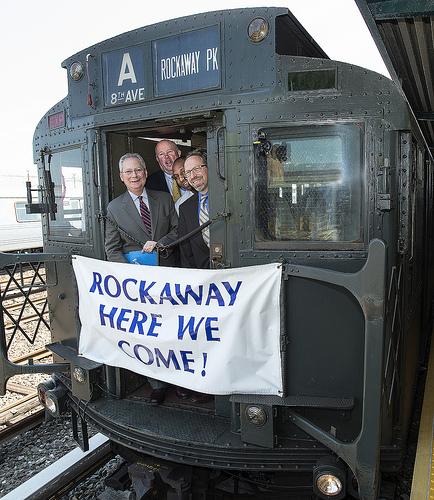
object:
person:
[101, 151, 180, 267]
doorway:
[100, 122, 221, 418]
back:
[30, 6, 399, 500]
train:
[24, 6, 433, 499]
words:
[86, 272, 244, 379]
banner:
[69, 253, 287, 398]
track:
[1, 432, 111, 500]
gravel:
[0, 403, 123, 498]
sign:
[153, 23, 224, 100]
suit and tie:
[102, 188, 180, 267]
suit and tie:
[144, 173, 187, 202]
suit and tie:
[178, 195, 210, 266]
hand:
[140, 241, 157, 253]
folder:
[123, 249, 159, 267]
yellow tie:
[170, 173, 180, 202]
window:
[262, 125, 362, 241]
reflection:
[269, 165, 340, 236]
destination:
[91, 271, 244, 306]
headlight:
[316, 469, 345, 497]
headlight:
[41, 393, 59, 419]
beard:
[191, 182, 209, 193]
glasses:
[182, 163, 207, 179]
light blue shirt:
[197, 190, 211, 219]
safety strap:
[97, 211, 230, 251]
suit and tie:
[175, 186, 200, 215]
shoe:
[147, 387, 167, 405]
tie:
[136, 196, 154, 236]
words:
[107, 87, 148, 104]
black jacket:
[178, 195, 209, 270]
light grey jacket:
[102, 188, 180, 265]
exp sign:
[47, 111, 68, 130]